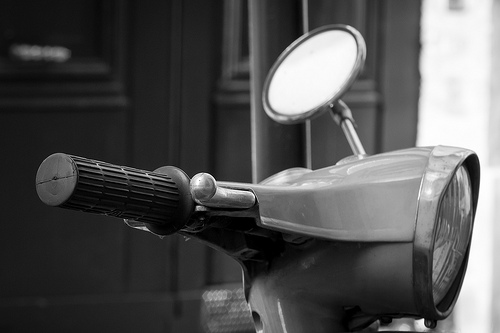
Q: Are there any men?
A: No, there are no men.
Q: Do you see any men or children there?
A: No, there are no men or children.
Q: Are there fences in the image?
A: No, there are no fences.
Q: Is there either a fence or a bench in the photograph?
A: No, there are no fences or benches.